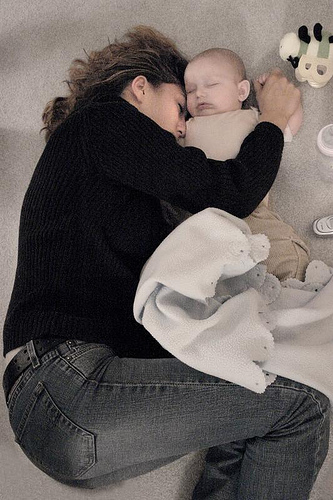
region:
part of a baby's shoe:
[309, 217, 332, 236]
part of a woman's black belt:
[0, 338, 62, 397]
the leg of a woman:
[9, 342, 332, 498]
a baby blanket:
[132, 207, 332, 398]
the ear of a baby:
[233, 77, 250, 103]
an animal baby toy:
[272, 25, 331, 85]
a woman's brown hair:
[40, 23, 189, 137]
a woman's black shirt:
[0, 83, 289, 361]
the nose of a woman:
[173, 116, 188, 135]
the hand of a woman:
[252, 71, 302, 120]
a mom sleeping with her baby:
[17, 45, 330, 487]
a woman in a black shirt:
[6, 99, 275, 338]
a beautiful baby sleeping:
[167, 45, 294, 252]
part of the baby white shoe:
[312, 213, 331, 235]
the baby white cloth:
[125, 208, 281, 385]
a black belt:
[2, 342, 58, 392]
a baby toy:
[277, 18, 330, 83]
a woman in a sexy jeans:
[17, 344, 323, 498]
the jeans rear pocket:
[16, 383, 94, 478]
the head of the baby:
[182, 48, 247, 116]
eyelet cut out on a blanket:
[258, 332, 274, 359]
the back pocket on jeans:
[25, 393, 106, 484]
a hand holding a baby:
[256, 72, 298, 124]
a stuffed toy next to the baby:
[283, 12, 331, 82]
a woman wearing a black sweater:
[6, 29, 291, 354]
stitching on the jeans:
[106, 376, 215, 393]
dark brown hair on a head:
[118, 34, 156, 69]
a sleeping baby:
[181, 38, 306, 277]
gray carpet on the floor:
[5, 13, 82, 68]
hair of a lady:
[109, 45, 124, 64]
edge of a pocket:
[67, 424, 94, 453]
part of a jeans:
[141, 420, 156, 442]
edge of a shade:
[191, 469, 194, 497]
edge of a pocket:
[89, 444, 96, 459]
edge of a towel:
[244, 376, 257, 389]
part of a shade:
[129, 467, 153, 486]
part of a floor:
[154, 472, 172, 491]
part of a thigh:
[151, 419, 172, 445]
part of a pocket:
[73, 445, 92, 473]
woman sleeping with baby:
[2, 28, 324, 498]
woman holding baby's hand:
[51, 25, 322, 238]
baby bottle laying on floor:
[310, 117, 332, 198]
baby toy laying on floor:
[271, 11, 327, 89]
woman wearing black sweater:
[9, 14, 327, 470]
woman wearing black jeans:
[0, 0, 326, 492]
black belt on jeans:
[0, 316, 325, 494]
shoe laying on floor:
[307, 197, 327, 238]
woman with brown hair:
[0, 12, 322, 497]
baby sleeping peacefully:
[167, 39, 316, 264]